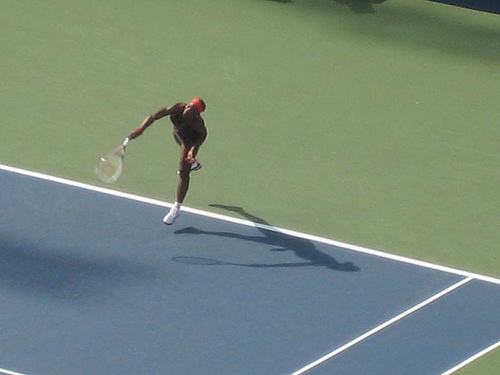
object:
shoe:
[161, 206, 180, 225]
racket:
[93, 129, 134, 185]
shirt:
[173, 119, 194, 130]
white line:
[448, 348, 496, 370]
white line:
[207, 206, 402, 271]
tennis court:
[1, 158, 500, 374]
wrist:
[135, 126, 146, 134]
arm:
[140, 104, 176, 130]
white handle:
[121, 137, 130, 146]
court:
[1, 249, 315, 341]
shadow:
[171, 203, 362, 273]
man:
[127, 97, 207, 226]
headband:
[191, 98, 204, 113]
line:
[371, 296, 434, 339]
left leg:
[176, 143, 200, 203]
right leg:
[172, 130, 182, 152]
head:
[182, 97, 206, 118]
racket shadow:
[171, 255, 250, 266]